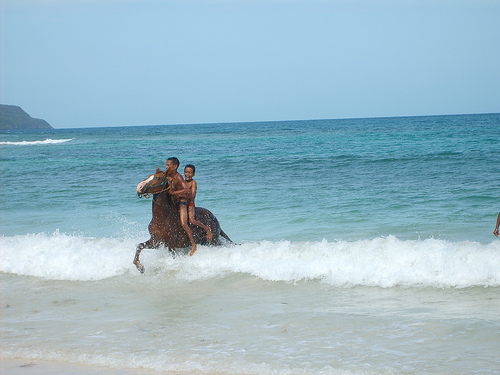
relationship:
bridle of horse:
[140, 180, 171, 193] [125, 157, 245, 278]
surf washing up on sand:
[0, 229, 499, 289] [9, 345, 91, 373]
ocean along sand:
[0, 112, 500, 374] [3, 351, 183, 372]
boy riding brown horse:
[184, 164, 212, 242] [133, 167, 232, 273]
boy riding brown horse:
[166, 157, 196, 256] [133, 167, 232, 273]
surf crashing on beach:
[0, 229, 499, 289] [4, 272, 499, 372]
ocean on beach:
[0, 112, 500, 374] [4, 121, 490, 373]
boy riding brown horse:
[180, 163, 217, 246] [133, 167, 232, 273]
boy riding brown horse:
[159, 150, 199, 256] [133, 167, 232, 273]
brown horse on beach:
[133, 167, 232, 273] [3, 220, 498, 374]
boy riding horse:
[180, 163, 217, 246] [126, 168, 242, 279]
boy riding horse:
[159, 150, 199, 256] [126, 168, 242, 279]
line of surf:
[5, 258, 495, 283] [0, 225, 499, 292]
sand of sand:
[0, 351, 193, 375] [3, 345, 141, 373]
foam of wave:
[2, 136, 81, 150] [9, 99, 497, 370]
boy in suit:
[184, 164, 212, 242] [186, 197, 198, 212]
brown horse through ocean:
[133, 167, 232, 273] [0, 112, 500, 374]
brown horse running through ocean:
[133, 167, 232, 273] [0, 114, 498, 374]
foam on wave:
[4, 230, 497, 290] [2, 220, 497, 303]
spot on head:
[141, 174, 157, 184] [133, 165, 174, 201]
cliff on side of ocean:
[0, 105, 52, 130] [0, 114, 498, 374]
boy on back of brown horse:
[166, 157, 196, 256] [133, 167, 232, 273]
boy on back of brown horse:
[184, 164, 212, 242] [133, 167, 232, 273]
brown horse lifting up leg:
[133, 167, 232, 273] [132, 237, 157, 282]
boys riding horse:
[166, 157, 212, 257] [115, 164, 236, 274]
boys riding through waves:
[166, 157, 212, 257] [1, 227, 497, 294]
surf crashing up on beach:
[0, 229, 499, 289] [0, 274, 500, 373]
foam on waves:
[0, 229, 500, 290] [1, 208, 498, 291]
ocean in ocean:
[0, 112, 500, 374] [5, 113, 497, 283]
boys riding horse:
[148, 142, 210, 251] [119, 173, 229, 263]